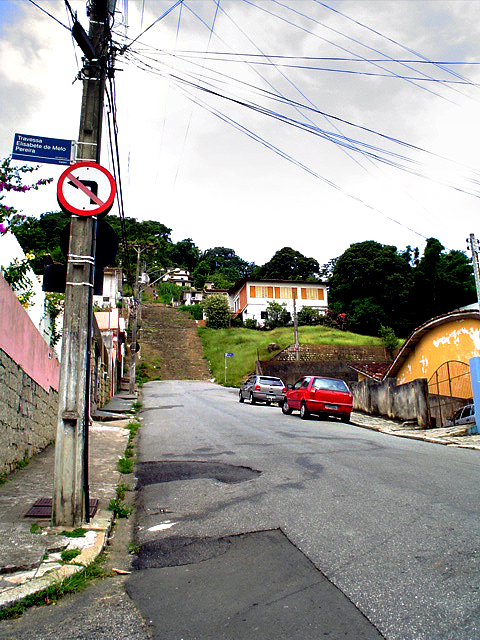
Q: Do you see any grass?
A: Yes, there is grass.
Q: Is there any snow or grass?
A: Yes, there is grass.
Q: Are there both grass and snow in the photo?
A: No, there is grass but no snow.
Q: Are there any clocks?
A: No, there are no clocks.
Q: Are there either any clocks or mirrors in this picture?
A: No, there are no clocks or mirrors.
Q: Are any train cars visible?
A: No, there are no train cars.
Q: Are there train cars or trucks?
A: No, there are no train cars or trucks.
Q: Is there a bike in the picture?
A: No, there are no bikes.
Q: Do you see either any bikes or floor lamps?
A: No, there are no bikes or floor lamps.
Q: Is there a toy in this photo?
A: No, there are no toys.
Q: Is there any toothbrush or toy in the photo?
A: No, there are no toys or toothbrushes.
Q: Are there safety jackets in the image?
A: No, there are no safety jackets.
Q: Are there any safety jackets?
A: No, there are no safety jackets.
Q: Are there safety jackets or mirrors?
A: No, there are no safety jackets or mirrors.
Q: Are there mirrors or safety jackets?
A: No, there are no safety jackets or mirrors.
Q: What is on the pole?
A: The sign is on the pole.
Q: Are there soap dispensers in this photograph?
A: No, there are no soap dispensers.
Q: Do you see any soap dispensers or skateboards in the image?
A: No, there are no soap dispensers or skateboards.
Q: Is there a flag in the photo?
A: No, there are no flags.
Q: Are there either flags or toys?
A: No, there are no flags or toys.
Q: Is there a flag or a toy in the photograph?
A: No, there are no flags or toys.